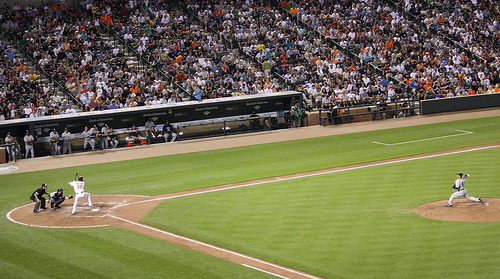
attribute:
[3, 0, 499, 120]
crowd — big, massive, large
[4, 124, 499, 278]
field — long, brown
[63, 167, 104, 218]
man — playing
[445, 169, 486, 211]
pitcher — white, tall, pitching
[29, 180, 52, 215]
umpire — looking, watching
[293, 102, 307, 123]
shirt — green, tee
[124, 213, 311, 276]
chalk — white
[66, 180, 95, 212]
uniform — white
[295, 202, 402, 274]
grass — green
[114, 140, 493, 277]
lines — white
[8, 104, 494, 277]
game — baseball